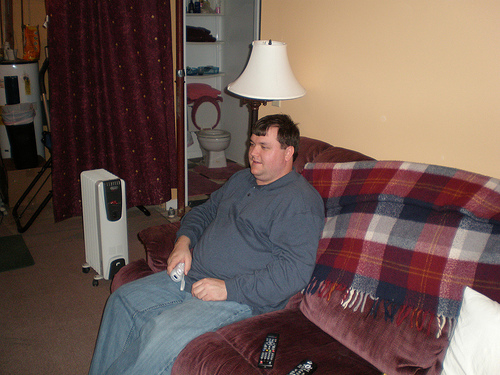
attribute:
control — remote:
[287, 332, 322, 372]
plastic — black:
[287, 354, 317, 370]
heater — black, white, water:
[11, 39, 43, 172]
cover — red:
[188, 92, 224, 130]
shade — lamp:
[224, 28, 312, 110]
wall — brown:
[285, 12, 483, 160]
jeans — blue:
[79, 265, 275, 370]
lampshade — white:
[213, 27, 308, 106]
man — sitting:
[86, 116, 383, 372]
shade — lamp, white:
[220, 28, 310, 104]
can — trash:
[8, 113, 48, 167]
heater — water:
[8, 48, 53, 168]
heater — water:
[1, 59, 68, 174]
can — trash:
[7, 96, 40, 166]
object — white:
[69, 165, 153, 282]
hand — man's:
[157, 236, 204, 278]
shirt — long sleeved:
[165, 157, 297, 344]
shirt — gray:
[188, 162, 344, 316]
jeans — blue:
[110, 273, 239, 369]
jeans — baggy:
[103, 279, 204, 364]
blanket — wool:
[319, 182, 499, 278]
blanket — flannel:
[308, 170, 462, 320]